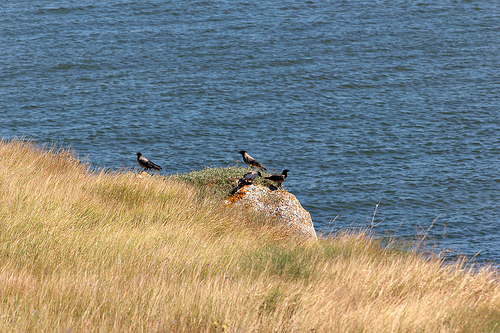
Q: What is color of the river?
A: Blue.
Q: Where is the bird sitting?
A: In rock.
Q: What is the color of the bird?
A: Black.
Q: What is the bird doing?
A: Standing in the rock.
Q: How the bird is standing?
A: With legs.